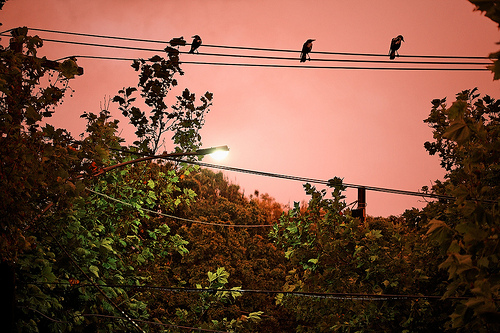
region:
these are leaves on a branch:
[86, 195, 133, 240]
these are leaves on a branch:
[194, 243, 229, 295]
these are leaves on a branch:
[256, 206, 325, 275]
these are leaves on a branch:
[319, 199, 393, 286]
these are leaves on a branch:
[109, 62, 171, 134]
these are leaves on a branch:
[170, 95, 205, 158]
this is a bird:
[368, 28, 425, 82]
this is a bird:
[286, 21, 338, 92]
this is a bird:
[166, 11, 247, 73]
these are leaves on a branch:
[116, 77, 156, 144]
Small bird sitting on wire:
[292, 36, 324, 64]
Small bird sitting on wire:
[190, 36, 202, 56]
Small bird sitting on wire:
[383, 31, 412, 67]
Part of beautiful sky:
[82, 12, 154, 30]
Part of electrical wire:
[236, 168, 288, 182]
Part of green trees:
[100, 225, 159, 267]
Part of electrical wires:
[222, 41, 272, 71]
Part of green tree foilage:
[188, 276, 245, 312]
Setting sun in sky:
[200, 147, 243, 167]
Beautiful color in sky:
[366, 81, 422, 121]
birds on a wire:
[166, 23, 454, 78]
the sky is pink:
[104, 14, 482, 224]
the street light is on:
[136, 121, 282, 199]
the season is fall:
[38, 42, 489, 289]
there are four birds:
[146, 19, 473, 70]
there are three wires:
[114, 9, 494, 103]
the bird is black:
[377, 22, 422, 77]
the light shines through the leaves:
[193, 257, 267, 304]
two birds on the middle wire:
[112, 12, 450, 82]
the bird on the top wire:
[366, 20, 434, 97]